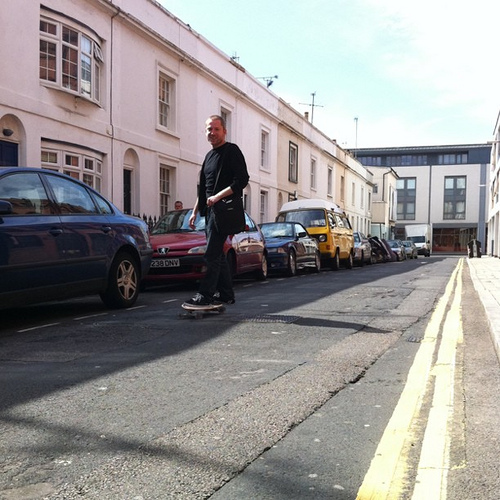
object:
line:
[386, 257, 464, 487]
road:
[2, 255, 500, 500]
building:
[343, 143, 493, 256]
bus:
[272, 199, 356, 271]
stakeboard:
[176, 302, 226, 319]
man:
[181, 114, 250, 310]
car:
[146, 207, 268, 287]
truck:
[404, 223, 432, 257]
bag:
[213, 143, 247, 235]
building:
[0, 0, 376, 237]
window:
[38, 3, 107, 110]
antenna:
[298, 91, 324, 124]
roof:
[278, 198, 344, 214]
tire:
[100, 251, 142, 308]